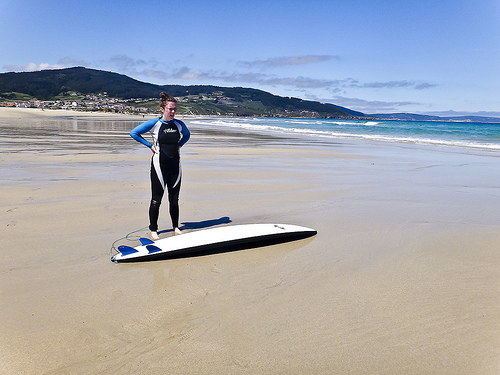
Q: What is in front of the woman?
A: A surfboard.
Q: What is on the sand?
A: A surfboard.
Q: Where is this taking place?
A: A beach.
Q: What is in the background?
A: Mountains.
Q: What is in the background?
A: Water.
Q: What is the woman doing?
A: Waiting to go surf.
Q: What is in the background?
A: Other buildings.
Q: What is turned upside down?
A: The surfboard.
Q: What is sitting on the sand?
A: A surfboard.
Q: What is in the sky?
A: Clouds.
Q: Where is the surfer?
A: Sand.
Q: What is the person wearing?
A: A wetsuit.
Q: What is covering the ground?
A: Sand.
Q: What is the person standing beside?
A: A surfboard.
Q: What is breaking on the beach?
A: Waves.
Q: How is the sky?
A: Blue with a few clouds.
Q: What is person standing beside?
A: Surfboard.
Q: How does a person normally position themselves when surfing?
A: By standing.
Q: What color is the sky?
A: Blue.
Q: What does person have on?
A: Wetsuit.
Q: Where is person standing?
A: Sand.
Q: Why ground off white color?
A: It's sand.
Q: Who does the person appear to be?
A: Woman.